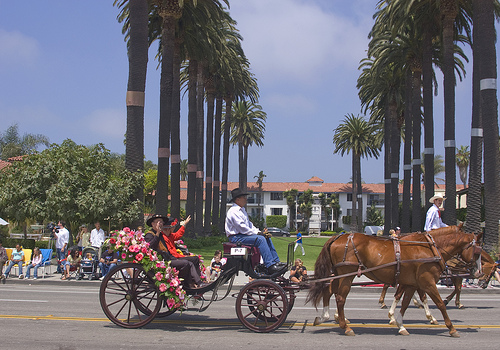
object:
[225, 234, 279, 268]
pants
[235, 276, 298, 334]
wheels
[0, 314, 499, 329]
lines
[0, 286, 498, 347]
asphalt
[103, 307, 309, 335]
shadow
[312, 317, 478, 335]
shadow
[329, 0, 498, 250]
trees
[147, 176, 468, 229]
house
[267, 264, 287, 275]
feet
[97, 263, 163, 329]
wheel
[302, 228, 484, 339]
horse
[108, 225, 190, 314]
flowers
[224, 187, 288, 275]
guy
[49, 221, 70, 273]
person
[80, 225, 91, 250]
person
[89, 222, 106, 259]
person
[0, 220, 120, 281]
audience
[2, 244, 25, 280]
kid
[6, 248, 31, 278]
chair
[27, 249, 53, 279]
chair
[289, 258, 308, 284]
person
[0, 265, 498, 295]
sidewalk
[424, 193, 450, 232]
man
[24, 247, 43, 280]
girl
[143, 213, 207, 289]
man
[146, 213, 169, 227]
hat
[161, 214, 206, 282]
person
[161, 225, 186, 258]
clothes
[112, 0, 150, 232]
palm tree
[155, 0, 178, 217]
palm tree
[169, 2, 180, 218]
palm tree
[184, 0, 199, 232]
palm tree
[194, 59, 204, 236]
palm tree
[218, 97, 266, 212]
palm trees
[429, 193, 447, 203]
hat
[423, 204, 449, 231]
shirt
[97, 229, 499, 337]
carriage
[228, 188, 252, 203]
hat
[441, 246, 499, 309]
horse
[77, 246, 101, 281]
stroller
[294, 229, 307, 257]
man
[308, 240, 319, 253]
grass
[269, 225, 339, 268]
field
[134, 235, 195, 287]
chair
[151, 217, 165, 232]
hand